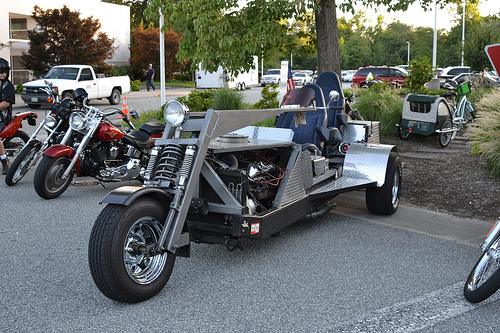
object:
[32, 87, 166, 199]
bike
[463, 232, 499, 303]
tire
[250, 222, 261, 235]
sticker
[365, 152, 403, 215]
tire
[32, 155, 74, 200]
tire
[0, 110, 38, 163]
bike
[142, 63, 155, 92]
man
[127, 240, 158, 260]
rim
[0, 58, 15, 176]
person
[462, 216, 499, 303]
motorcycle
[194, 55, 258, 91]
car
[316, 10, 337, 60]
trunk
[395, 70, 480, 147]
bicycle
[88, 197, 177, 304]
tire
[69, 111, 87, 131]
light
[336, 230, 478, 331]
road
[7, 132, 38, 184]
tire bike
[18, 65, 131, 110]
car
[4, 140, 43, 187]
tire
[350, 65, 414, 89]
car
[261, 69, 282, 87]
car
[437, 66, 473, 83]
car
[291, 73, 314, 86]
car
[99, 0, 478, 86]
tree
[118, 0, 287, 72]
leaves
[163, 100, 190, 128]
light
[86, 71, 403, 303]
bike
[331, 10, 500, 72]
tree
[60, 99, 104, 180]
fork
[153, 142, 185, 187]
spring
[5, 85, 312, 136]
street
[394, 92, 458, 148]
holder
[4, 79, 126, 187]
bike